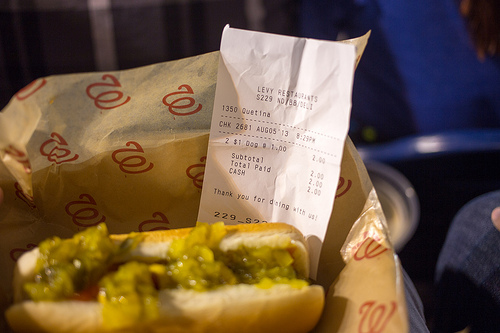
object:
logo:
[63, 192, 106, 228]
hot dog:
[99, 261, 167, 331]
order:
[228, 151, 273, 175]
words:
[220, 137, 286, 153]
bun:
[2, 222, 328, 332]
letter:
[111, 141, 155, 174]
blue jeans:
[429, 188, 500, 333]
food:
[3, 221, 326, 332]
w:
[161, 84, 201, 116]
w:
[39, 132, 79, 164]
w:
[63, 193, 107, 228]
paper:
[212, 86, 331, 226]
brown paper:
[1, 28, 431, 332]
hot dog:
[223, 237, 310, 290]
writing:
[221, 105, 271, 117]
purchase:
[198, 22, 358, 283]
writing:
[218, 121, 316, 143]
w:
[85, 73, 133, 110]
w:
[111, 141, 154, 175]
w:
[351, 230, 389, 260]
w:
[356, 299, 399, 333]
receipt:
[196, 23, 359, 284]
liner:
[38, 132, 80, 165]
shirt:
[292, 0, 500, 138]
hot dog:
[74, 222, 125, 278]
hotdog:
[157, 240, 243, 291]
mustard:
[186, 250, 232, 292]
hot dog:
[23, 233, 82, 302]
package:
[3, 29, 431, 331]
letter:
[161, 82, 203, 117]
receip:
[193, 23, 360, 284]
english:
[214, 187, 324, 222]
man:
[426, 192, 500, 333]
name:
[253, 85, 318, 110]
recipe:
[198, 25, 358, 285]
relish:
[27, 223, 313, 333]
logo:
[85, 73, 131, 110]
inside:
[24, 231, 310, 302]